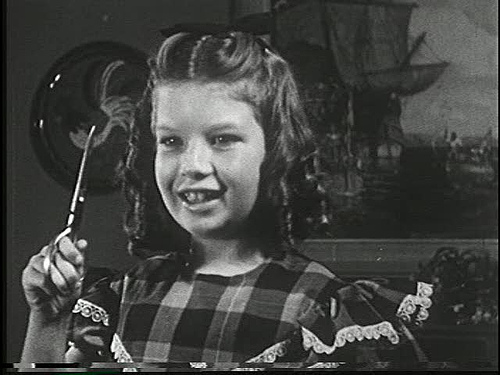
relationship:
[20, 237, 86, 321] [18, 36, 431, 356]
hand on girl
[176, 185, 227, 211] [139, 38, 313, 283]
smile of girl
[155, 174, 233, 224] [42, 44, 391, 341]
mouth of girl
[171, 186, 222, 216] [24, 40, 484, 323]
mouth of girl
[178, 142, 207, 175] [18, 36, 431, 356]
nose of girl